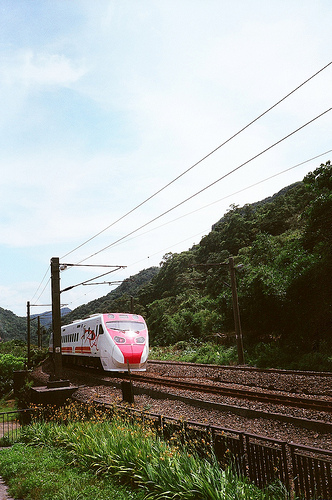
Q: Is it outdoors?
A: Yes, it is outdoors.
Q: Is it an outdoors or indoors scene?
A: It is outdoors.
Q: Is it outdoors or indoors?
A: It is outdoors.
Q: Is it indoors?
A: No, it is outdoors.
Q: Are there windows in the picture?
A: Yes, there is a window.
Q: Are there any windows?
A: Yes, there is a window.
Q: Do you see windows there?
A: Yes, there is a window.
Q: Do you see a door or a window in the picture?
A: Yes, there is a window.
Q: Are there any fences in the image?
A: Yes, there is a fence.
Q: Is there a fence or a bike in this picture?
A: Yes, there is a fence.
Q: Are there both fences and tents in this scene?
A: No, there is a fence but no tents.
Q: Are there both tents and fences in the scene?
A: No, there is a fence but no tents.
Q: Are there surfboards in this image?
A: No, there are no surfboards.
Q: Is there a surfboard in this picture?
A: No, there are no surfboards.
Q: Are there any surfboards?
A: No, there are no surfboards.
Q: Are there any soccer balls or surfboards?
A: No, there are no surfboards or soccer balls.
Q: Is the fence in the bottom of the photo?
A: Yes, the fence is in the bottom of the image.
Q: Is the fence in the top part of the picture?
A: No, the fence is in the bottom of the image.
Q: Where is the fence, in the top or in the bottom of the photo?
A: The fence is in the bottom of the image.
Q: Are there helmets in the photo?
A: No, there are no helmets.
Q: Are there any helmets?
A: No, there are no helmets.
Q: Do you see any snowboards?
A: No, there are no snowboards.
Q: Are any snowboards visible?
A: No, there are no snowboards.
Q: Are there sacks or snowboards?
A: No, there are no snowboards or sacks.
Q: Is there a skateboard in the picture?
A: No, there are no skateboards.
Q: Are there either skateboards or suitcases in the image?
A: No, there are no skateboards or suitcases.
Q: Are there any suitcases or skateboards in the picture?
A: No, there are no skateboards or suitcases.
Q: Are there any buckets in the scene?
A: No, there are no buckets.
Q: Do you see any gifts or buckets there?
A: No, there are no buckets or gifts.